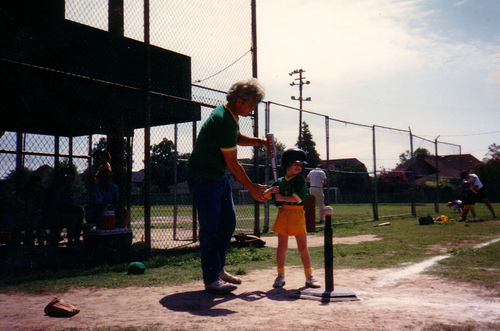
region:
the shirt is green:
[194, 111, 269, 205]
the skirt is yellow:
[244, 190, 372, 267]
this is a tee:
[297, 201, 394, 308]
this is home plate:
[128, 240, 475, 330]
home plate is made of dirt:
[211, 253, 382, 327]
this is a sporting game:
[47, 17, 467, 285]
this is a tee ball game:
[57, 53, 434, 324]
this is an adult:
[185, 85, 285, 269]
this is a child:
[257, 174, 332, 312]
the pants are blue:
[185, 155, 253, 279]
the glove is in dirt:
[34, 284, 121, 322]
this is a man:
[168, 50, 284, 302]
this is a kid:
[260, 103, 330, 328]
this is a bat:
[257, 110, 287, 200]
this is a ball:
[312, 192, 339, 219]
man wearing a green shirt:
[169, 91, 265, 198]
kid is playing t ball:
[138, 0, 462, 329]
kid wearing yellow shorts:
[263, 195, 310, 237]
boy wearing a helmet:
[270, 142, 316, 174]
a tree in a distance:
[477, 139, 499, 204]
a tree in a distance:
[440, 178, 450, 203]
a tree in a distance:
[393, 140, 430, 170]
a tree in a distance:
[348, 160, 384, 209]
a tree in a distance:
[295, 125, 332, 192]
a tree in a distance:
[378, 160, 413, 197]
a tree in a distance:
[146, 130, 201, 192]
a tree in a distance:
[100, 138, 146, 195]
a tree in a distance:
[53, 155, 92, 205]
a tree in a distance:
[3, 153, 40, 202]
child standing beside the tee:
[260, 129, 320, 291]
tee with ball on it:
[315, 201, 358, 302]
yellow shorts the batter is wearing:
[267, 200, 307, 234]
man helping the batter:
[197, 73, 262, 294]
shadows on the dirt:
[156, 282, 356, 322]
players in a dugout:
[3, 65, 198, 255]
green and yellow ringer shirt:
[176, 102, 233, 179]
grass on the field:
[159, 209, 497, 289]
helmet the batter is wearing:
[278, 142, 306, 169]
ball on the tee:
[323, 205, 335, 217]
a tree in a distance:
[478, 141, 498, 191]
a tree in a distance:
[405, 138, 436, 167]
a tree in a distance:
[296, 120, 326, 167]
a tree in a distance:
[254, 134, 283, 159]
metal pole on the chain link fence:
[322, 114, 329, 200]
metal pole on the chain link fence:
[371, 125, 378, 220]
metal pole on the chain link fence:
[408, 127, 418, 221]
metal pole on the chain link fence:
[432, 138, 442, 215]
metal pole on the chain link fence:
[458, 143, 465, 211]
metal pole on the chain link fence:
[262, 100, 269, 230]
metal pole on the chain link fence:
[188, 117, 198, 240]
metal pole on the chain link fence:
[170, 121, 181, 241]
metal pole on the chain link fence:
[87, 132, 93, 165]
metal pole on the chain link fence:
[53, 133, 59, 166]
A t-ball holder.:
[305, 200, 358, 308]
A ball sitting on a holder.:
[297, 202, 359, 307]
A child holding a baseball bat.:
[255, 130, 317, 290]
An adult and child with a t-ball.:
[179, 74, 361, 305]